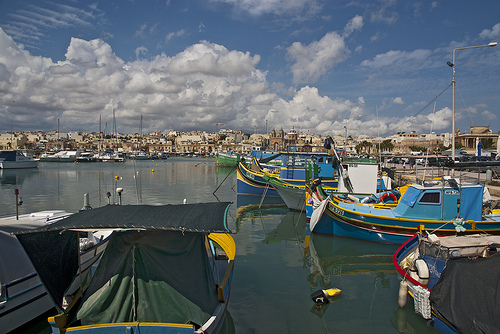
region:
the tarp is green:
[93, 248, 183, 321]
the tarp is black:
[441, 258, 483, 315]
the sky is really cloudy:
[265, 81, 392, 116]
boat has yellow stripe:
[362, 199, 400, 242]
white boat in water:
[11, 266, 36, 307]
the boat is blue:
[310, 182, 385, 232]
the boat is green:
[218, 141, 243, 174]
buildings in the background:
[136, 128, 243, 161]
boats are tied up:
[242, 141, 378, 258]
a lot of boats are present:
[26, 134, 401, 274]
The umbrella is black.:
[45, 182, 270, 253]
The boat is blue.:
[318, 172, 496, 231]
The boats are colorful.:
[216, 152, 496, 262]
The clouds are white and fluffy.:
[7, 29, 367, 168]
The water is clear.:
[141, 154, 251, 209]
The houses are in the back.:
[41, 124, 498, 188]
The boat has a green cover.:
[55, 221, 244, 322]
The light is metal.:
[423, 30, 495, 135]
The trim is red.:
[375, 226, 440, 292]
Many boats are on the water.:
[9, 108, 498, 315]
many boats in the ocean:
[3, 145, 499, 331]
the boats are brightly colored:
[236, 147, 498, 232]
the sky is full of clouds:
[6, 0, 491, 137]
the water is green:
[7, 153, 444, 331]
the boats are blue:
[238, 149, 490, 243]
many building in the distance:
[2, 130, 497, 160]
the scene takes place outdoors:
[0, 0, 495, 330]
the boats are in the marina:
[0, 151, 496, 332]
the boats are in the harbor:
[0, 154, 499, 331]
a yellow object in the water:
[313, 284, 344, 305]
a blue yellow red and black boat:
[314, 172, 496, 251]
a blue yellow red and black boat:
[228, 158, 342, 201]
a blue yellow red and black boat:
[252, 168, 442, 212]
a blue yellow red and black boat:
[390, 226, 498, 330]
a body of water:
[11, 152, 436, 329]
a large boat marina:
[6, 140, 491, 324]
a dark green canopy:
[53, 196, 234, 239]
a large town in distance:
[3, 124, 453, 157]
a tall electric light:
[446, 34, 496, 166]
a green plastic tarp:
[76, 231, 216, 332]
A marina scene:
[16, 65, 478, 305]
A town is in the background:
[4, 122, 453, 157]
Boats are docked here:
[239, 134, 499, 271]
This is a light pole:
[439, 25, 499, 161]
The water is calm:
[243, 226, 310, 307]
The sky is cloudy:
[25, 20, 352, 129]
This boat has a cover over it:
[51, 200, 252, 331]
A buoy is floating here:
[304, 274, 346, 316]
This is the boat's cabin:
[396, 182, 486, 219]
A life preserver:
[409, 255, 432, 285]